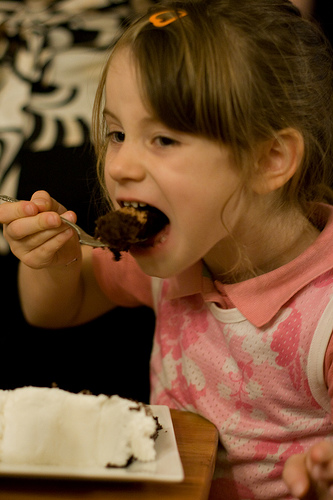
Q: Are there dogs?
A: No, there are no dogs.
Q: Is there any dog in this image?
A: No, there are no dogs.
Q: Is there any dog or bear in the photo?
A: No, there are no dogs or bears.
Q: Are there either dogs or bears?
A: No, there are no dogs or bears.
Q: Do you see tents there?
A: No, there are no tents.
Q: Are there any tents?
A: No, there are no tents.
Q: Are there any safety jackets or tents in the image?
A: No, there are no tents or safety jackets.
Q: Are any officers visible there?
A: No, there are no officers.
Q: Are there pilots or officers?
A: No, there are no officers or pilots.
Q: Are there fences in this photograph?
A: No, there are no fences.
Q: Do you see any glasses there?
A: No, there are no glasses.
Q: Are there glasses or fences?
A: No, there are no glasses or fences.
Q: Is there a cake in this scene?
A: Yes, there is a cake.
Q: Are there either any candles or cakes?
A: Yes, there is a cake.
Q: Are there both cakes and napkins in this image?
A: No, there is a cake but no napkins.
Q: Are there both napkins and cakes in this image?
A: No, there is a cake but no napkins.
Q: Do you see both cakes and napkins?
A: No, there is a cake but no napkins.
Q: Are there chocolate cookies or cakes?
A: Yes, there is a chocolate cake.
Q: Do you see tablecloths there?
A: No, there are no tablecloths.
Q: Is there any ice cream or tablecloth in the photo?
A: No, there are no tablecloths or ice cream.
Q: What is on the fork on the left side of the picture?
A: The cake is on the fork.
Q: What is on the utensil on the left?
A: The cake is on the fork.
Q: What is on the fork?
A: The cake is on the fork.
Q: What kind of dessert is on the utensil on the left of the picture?
A: The dessert is a cake.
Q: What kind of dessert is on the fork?
A: The dessert is a cake.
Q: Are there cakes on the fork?
A: Yes, there is a cake on the fork.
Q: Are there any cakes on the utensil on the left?
A: Yes, there is a cake on the fork.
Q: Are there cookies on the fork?
A: No, there is a cake on the fork.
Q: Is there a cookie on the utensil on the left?
A: No, there is a cake on the fork.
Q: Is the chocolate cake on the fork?
A: Yes, the cake is on the fork.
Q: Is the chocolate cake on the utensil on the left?
A: Yes, the cake is on the fork.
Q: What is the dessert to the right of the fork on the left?
A: The dessert is a cake.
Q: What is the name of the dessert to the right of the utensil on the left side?
A: The dessert is a cake.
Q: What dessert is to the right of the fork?
A: The dessert is a cake.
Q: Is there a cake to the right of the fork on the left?
A: Yes, there is a cake to the right of the fork.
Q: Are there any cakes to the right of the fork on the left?
A: Yes, there is a cake to the right of the fork.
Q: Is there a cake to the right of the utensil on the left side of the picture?
A: Yes, there is a cake to the right of the fork.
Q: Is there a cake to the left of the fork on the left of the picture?
A: No, the cake is to the right of the fork.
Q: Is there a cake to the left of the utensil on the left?
A: No, the cake is to the right of the fork.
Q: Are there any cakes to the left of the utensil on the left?
A: No, the cake is to the right of the fork.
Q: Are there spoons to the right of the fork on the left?
A: No, there is a cake to the right of the fork.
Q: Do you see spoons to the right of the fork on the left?
A: No, there is a cake to the right of the fork.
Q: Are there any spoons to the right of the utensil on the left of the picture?
A: No, there is a cake to the right of the fork.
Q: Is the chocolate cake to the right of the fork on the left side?
A: Yes, the cake is to the right of the fork.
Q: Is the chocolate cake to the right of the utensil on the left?
A: Yes, the cake is to the right of the fork.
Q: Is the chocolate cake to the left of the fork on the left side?
A: No, the cake is to the right of the fork.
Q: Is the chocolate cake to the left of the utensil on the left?
A: No, the cake is to the right of the fork.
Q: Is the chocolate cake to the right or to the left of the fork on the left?
A: The cake is to the right of the fork.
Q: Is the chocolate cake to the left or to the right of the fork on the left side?
A: The cake is to the right of the fork.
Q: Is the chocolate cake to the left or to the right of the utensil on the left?
A: The cake is to the right of the fork.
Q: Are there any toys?
A: No, there are no toys.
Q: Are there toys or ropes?
A: No, there are no toys or ropes.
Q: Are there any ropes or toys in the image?
A: No, there are no toys or ropes.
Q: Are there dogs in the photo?
A: No, there are no dogs.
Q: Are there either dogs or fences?
A: No, there are no dogs or fences.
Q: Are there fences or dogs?
A: No, there are no dogs or fences.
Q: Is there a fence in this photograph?
A: No, there are no fences.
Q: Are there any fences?
A: No, there are no fences.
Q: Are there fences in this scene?
A: No, there are no fences.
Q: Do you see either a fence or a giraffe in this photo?
A: No, there are no fences or giraffes.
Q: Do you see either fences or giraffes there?
A: No, there are no fences or giraffes.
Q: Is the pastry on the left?
A: Yes, the pastry is on the left of the image.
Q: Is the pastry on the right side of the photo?
A: No, the pastry is on the left of the image.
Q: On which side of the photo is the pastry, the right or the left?
A: The pastry is on the left of the image.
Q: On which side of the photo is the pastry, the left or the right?
A: The pastry is on the left of the image.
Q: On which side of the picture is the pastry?
A: The pastry is on the left of the image.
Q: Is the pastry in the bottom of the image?
A: Yes, the pastry is in the bottom of the image.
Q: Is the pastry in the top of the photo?
A: No, the pastry is in the bottom of the image.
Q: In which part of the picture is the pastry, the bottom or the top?
A: The pastry is in the bottom of the image.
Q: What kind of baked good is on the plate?
A: The food is a pastry.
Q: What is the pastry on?
A: The pastry is on the plate.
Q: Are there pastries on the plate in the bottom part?
A: Yes, there is a pastry on the plate.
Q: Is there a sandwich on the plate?
A: No, there is a pastry on the plate.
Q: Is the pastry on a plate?
A: Yes, the pastry is on a plate.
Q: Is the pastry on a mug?
A: No, the pastry is on a plate.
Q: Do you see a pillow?
A: No, there are no pillows.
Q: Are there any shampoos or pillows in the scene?
A: No, there are no pillows or shampoos.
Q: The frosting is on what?
A: The frosting is on the plate.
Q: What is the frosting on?
A: The frosting is on the plate.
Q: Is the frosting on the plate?
A: Yes, the frosting is on the plate.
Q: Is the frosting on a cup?
A: No, the frosting is on the plate.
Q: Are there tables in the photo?
A: Yes, there is a table.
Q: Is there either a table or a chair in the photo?
A: Yes, there is a table.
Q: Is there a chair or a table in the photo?
A: Yes, there is a table.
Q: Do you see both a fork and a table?
A: Yes, there are both a table and a fork.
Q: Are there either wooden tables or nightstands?
A: Yes, there is a wood table.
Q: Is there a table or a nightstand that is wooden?
A: Yes, the table is wooden.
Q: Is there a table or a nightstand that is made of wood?
A: Yes, the table is made of wood.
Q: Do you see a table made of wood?
A: Yes, there is a table that is made of wood.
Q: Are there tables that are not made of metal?
A: Yes, there is a table that is made of wood.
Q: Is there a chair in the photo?
A: No, there are no chairs.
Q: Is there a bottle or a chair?
A: No, there are no chairs or bottles.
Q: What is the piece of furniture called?
A: The piece of furniture is a table.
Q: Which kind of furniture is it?
A: The piece of furniture is a table.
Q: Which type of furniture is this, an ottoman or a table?
A: That is a table.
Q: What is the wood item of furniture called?
A: The piece of furniture is a table.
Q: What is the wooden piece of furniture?
A: The piece of furniture is a table.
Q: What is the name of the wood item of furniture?
A: The piece of furniture is a table.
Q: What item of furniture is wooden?
A: The piece of furniture is a table.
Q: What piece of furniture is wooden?
A: The piece of furniture is a table.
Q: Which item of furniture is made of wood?
A: The piece of furniture is a table.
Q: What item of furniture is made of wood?
A: The piece of furniture is a table.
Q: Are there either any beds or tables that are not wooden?
A: No, there is a table but it is wooden.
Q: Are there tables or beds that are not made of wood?
A: No, there is a table but it is made of wood.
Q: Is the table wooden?
A: Yes, the table is wooden.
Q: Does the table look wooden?
A: Yes, the table is wooden.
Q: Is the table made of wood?
A: Yes, the table is made of wood.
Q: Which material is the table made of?
A: The table is made of wood.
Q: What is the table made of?
A: The table is made of wood.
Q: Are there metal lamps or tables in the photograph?
A: No, there is a table but it is wooden.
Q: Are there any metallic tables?
A: No, there is a table but it is wooden.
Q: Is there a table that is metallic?
A: No, there is a table but it is wooden.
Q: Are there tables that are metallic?
A: No, there is a table but it is wooden.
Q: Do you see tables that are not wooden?
A: No, there is a table but it is wooden.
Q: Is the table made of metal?
A: No, the table is made of wood.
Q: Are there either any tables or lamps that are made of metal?
A: No, there is a table but it is made of wood.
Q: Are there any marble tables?
A: No, there is a table but it is made of wood.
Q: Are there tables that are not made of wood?
A: No, there is a table but it is made of wood.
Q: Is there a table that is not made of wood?
A: No, there is a table but it is made of wood.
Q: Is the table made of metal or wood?
A: The table is made of wood.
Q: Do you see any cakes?
A: Yes, there is a cake.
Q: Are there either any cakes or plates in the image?
A: Yes, there is a cake.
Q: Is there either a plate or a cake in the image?
A: Yes, there is a cake.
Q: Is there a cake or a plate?
A: Yes, there is a cake.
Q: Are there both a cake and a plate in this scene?
A: Yes, there are both a cake and a plate.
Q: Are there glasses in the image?
A: No, there are no glasses.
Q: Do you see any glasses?
A: No, there are no glasses.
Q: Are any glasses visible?
A: No, there are no glasses.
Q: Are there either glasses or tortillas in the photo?
A: No, there are no glasses or tortillas.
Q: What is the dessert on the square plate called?
A: The dessert is a cake.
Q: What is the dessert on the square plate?
A: The dessert is a cake.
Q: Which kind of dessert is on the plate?
A: The dessert is a cake.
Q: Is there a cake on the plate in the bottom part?
A: Yes, there is a cake on the plate.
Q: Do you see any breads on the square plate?
A: No, there is a cake on the plate.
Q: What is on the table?
A: The cake is on the table.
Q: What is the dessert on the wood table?
A: The dessert is a cake.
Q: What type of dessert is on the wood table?
A: The dessert is a cake.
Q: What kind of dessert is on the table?
A: The dessert is a cake.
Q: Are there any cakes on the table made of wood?
A: Yes, there is a cake on the table.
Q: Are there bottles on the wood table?
A: No, there is a cake on the table.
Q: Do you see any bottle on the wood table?
A: No, there is a cake on the table.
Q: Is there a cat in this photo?
A: No, there are no cats.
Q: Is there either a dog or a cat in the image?
A: No, there are no cats or dogs.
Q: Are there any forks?
A: Yes, there is a fork.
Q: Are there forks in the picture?
A: Yes, there is a fork.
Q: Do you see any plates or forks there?
A: Yes, there is a fork.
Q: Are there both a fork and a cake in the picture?
A: Yes, there are both a fork and a cake.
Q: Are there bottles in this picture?
A: No, there are no bottles.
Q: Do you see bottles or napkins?
A: No, there are no bottles or napkins.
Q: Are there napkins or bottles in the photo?
A: No, there are no bottles or napkins.